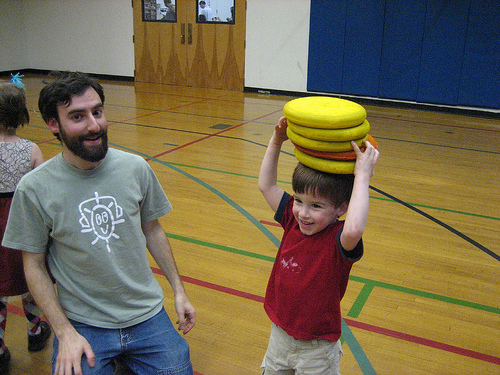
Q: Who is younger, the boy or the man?
A: The boy is younger than the man.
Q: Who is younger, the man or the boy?
A: The boy is younger than the man.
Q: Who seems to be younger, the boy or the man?
A: The boy is younger than the man.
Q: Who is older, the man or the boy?
A: The man is older than the boy.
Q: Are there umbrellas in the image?
A: No, there are no umbrellas.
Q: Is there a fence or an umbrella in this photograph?
A: No, there are no umbrellas or fences.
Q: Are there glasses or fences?
A: No, there are no glasses or fences.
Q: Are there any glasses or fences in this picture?
A: No, there are no fences or glasses.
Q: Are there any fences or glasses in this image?
A: No, there are no fences or glasses.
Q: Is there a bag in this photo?
A: No, there are no bags.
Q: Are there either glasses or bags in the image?
A: No, there are no bags or glasses.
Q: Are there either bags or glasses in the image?
A: No, there are no bags or glasses.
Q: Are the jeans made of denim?
A: Yes, the jeans are made of denim.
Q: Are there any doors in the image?
A: Yes, there are doors.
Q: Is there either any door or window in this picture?
A: Yes, there are doors.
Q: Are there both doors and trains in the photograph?
A: No, there are doors but no trains.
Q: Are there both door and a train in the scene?
A: No, there are doors but no trains.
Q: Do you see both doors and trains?
A: No, there are doors but no trains.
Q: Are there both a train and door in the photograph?
A: No, there are doors but no trains.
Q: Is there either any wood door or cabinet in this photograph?
A: Yes, there are wood doors.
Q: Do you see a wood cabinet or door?
A: Yes, there are wood doors.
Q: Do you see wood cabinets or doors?
A: Yes, there are wood doors.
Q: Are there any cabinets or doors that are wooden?
A: Yes, the doors are wooden.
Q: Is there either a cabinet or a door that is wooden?
A: Yes, the doors are wooden.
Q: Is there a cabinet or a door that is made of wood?
A: Yes, the doors are made of wood.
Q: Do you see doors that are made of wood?
A: Yes, there are doors that are made of wood.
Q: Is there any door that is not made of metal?
A: Yes, there are doors that are made of wood.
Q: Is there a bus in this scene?
A: No, there are no buses.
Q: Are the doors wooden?
A: Yes, the doors are wooden.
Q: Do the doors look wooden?
A: Yes, the doors are wooden.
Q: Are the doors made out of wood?
A: Yes, the doors are made of wood.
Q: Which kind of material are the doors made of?
A: The doors are made of wood.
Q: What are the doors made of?
A: The doors are made of wood.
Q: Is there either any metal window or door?
A: No, there are doors but they are wooden.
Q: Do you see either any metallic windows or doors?
A: No, there are doors but they are wooden.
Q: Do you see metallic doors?
A: No, there are doors but they are wooden.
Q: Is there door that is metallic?
A: No, there are doors but they are wooden.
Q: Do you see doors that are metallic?
A: No, there are doors but they are wooden.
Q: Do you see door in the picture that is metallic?
A: No, there are doors but they are wooden.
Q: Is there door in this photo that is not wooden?
A: No, there are doors but they are wooden.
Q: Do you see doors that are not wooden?
A: No, there are doors but they are wooden.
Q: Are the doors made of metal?
A: No, the doors are made of wood.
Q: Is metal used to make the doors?
A: No, the doors are made of wood.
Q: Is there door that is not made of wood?
A: No, there are doors but they are made of wood.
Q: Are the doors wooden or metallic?
A: The doors are wooden.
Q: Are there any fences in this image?
A: No, there are no fences.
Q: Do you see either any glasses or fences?
A: No, there are no fences or glasses.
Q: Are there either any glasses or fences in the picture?
A: No, there are no fences or glasses.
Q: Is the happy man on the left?
A: Yes, the man is on the left of the image.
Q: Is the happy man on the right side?
A: No, the man is on the left of the image.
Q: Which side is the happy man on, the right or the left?
A: The man is on the left of the image.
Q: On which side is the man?
A: The man is on the left of the image.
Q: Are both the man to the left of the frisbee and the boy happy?
A: Yes, both the man and the boy are happy.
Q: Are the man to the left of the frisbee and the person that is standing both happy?
A: Yes, both the man and the boy are happy.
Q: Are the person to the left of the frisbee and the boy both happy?
A: Yes, both the man and the boy are happy.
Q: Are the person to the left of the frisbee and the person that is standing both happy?
A: Yes, both the man and the boy are happy.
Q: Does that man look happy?
A: Yes, the man is happy.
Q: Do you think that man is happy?
A: Yes, the man is happy.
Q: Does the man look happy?
A: Yes, the man is happy.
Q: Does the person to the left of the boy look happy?
A: Yes, the man is happy.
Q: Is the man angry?
A: No, the man is happy.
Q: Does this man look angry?
A: No, the man is happy.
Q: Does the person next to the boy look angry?
A: No, the man is happy.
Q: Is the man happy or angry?
A: The man is happy.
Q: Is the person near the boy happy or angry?
A: The man is happy.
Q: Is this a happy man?
A: Yes, this is a happy man.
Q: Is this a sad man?
A: No, this is a happy man.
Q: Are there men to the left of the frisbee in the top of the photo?
A: Yes, there is a man to the left of the frisbee.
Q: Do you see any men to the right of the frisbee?
A: No, the man is to the left of the frisbee.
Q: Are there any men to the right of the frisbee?
A: No, the man is to the left of the frisbee.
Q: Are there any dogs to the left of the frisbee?
A: No, there is a man to the left of the frisbee.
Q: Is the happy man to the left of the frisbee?
A: Yes, the man is to the left of the frisbee.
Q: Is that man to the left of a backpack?
A: No, the man is to the left of the frisbee.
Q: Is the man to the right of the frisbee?
A: No, the man is to the left of the frisbee.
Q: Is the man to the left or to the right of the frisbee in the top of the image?
A: The man is to the left of the frisbee.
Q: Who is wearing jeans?
A: The man is wearing jeans.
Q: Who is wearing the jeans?
A: The man is wearing jeans.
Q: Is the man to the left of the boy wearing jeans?
A: Yes, the man is wearing jeans.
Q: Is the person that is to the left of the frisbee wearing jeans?
A: Yes, the man is wearing jeans.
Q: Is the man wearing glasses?
A: No, the man is wearing jeans.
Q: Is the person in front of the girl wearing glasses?
A: No, the man is wearing jeans.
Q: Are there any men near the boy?
A: Yes, there is a man near the boy.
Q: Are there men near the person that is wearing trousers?
A: Yes, there is a man near the boy.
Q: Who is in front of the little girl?
A: The man is in front of the girl.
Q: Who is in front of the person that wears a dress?
A: The man is in front of the girl.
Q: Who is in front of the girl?
A: The man is in front of the girl.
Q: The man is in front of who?
A: The man is in front of the girl.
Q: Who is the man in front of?
A: The man is in front of the girl.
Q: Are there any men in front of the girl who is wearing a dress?
A: Yes, there is a man in front of the girl.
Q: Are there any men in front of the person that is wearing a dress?
A: Yes, there is a man in front of the girl.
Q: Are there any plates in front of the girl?
A: No, there is a man in front of the girl.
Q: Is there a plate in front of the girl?
A: No, there is a man in front of the girl.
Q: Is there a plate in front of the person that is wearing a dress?
A: No, there is a man in front of the girl.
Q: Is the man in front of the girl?
A: Yes, the man is in front of the girl.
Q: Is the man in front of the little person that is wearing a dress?
A: Yes, the man is in front of the girl.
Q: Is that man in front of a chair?
A: No, the man is in front of the girl.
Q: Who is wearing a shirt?
A: The man is wearing a shirt.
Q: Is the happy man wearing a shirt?
A: Yes, the man is wearing a shirt.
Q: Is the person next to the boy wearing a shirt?
A: Yes, the man is wearing a shirt.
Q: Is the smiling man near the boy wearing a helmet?
A: No, the man is wearing a shirt.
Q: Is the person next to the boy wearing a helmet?
A: No, the man is wearing a shirt.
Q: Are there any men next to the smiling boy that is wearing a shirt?
A: Yes, there is a man next to the boy.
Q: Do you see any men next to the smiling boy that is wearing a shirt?
A: Yes, there is a man next to the boy.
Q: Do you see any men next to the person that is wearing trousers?
A: Yes, there is a man next to the boy.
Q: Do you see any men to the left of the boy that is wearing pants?
A: Yes, there is a man to the left of the boy.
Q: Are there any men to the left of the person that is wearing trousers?
A: Yes, there is a man to the left of the boy.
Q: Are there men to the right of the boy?
A: No, the man is to the left of the boy.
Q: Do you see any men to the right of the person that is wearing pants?
A: No, the man is to the left of the boy.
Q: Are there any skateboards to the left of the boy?
A: No, there is a man to the left of the boy.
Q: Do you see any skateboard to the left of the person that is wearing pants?
A: No, there is a man to the left of the boy.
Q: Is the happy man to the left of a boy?
A: Yes, the man is to the left of a boy.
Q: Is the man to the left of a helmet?
A: No, the man is to the left of a boy.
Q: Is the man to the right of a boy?
A: No, the man is to the left of a boy.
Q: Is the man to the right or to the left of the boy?
A: The man is to the left of the boy.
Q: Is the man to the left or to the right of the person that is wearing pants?
A: The man is to the left of the boy.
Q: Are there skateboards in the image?
A: No, there are no skateboards.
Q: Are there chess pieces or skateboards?
A: No, there are no skateboards or chess pieces.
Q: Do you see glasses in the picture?
A: No, there are no glasses.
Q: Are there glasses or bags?
A: No, there are no glasses or bags.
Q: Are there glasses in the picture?
A: No, there are no glasses.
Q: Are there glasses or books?
A: No, there are no glasses or books.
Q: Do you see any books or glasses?
A: No, there are no glasses or books.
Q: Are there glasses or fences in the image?
A: No, there are no glasses or fences.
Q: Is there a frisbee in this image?
A: Yes, there is a frisbee.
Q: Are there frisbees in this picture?
A: Yes, there is a frisbee.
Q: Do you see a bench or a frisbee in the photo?
A: Yes, there is a frisbee.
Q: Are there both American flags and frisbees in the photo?
A: No, there is a frisbee but no American flags.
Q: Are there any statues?
A: No, there are no statues.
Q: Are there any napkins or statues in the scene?
A: No, there are no statues or napkins.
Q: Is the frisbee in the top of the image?
A: Yes, the frisbee is in the top of the image.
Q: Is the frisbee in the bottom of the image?
A: No, the frisbee is in the top of the image.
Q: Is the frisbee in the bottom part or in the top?
A: The frisbee is in the top of the image.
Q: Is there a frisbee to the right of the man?
A: Yes, there is a frisbee to the right of the man.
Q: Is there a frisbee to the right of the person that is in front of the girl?
A: Yes, there is a frisbee to the right of the man.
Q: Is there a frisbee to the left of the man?
A: No, the frisbee is to the right of the man.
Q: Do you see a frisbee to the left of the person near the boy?
A: No, the frisbee is to the right of the man.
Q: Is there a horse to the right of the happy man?
A: No, there is a frisbee to the right of the man.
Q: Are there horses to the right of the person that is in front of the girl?
A: No, there is a frisbee to the right of the man.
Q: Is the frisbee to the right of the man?
A: Yes, the frisbee is to the right of the man.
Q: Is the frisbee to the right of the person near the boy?
A: Yes, the frisbee is to the right of the man.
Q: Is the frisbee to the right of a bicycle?
A: No, the frisbee is to the right of the man.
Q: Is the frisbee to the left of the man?
A: No, the frisbee is to the right of the man.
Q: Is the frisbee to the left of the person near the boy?
A: No, the frisbee is to the right of the man.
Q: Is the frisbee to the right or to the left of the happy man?
A: The frisbee is to the right of the man.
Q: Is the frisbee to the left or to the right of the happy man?
A: The frisbee is to the right of the man.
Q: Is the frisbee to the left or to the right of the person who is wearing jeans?
A: The frisbee is to the right of the man.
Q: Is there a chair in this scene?
A: No, there are no chairs.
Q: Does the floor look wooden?
A: Yes, the floor is wooden.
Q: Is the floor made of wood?
A: Yes, the floor is made of wood.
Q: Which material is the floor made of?
A: The floor is made of wood.